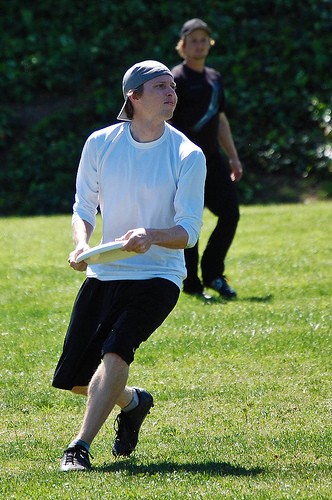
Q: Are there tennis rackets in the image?
A: No, there are no tennis rackets.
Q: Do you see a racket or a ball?
A: No, there are no rackets or balls.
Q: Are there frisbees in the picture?
A: Yes, there is a frisbee.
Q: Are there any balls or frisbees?
A: Yes, there is a frisbee.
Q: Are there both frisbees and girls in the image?
A: No, there is a frisbee but no girls.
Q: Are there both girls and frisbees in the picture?
A: No, there is a frisbee but no girls.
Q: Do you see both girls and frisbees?
A: No, there is a frisbee but no girls.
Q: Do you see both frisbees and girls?
A: No, there is a frisbee but no girls.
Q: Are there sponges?
A: No, there are no sponges.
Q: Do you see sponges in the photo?
A: No, there are no sponges.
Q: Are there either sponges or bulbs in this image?
A: No, there are no sponges or bulbs.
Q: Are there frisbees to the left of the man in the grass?
A: Yes, there is a frisbee to the left of the man.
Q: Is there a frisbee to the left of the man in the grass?
A: Yes, there is a frisbee to the left of the man.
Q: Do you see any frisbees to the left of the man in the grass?
A: Yes, there is a frisbee to the left of the man.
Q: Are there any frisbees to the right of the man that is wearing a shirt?
A: No, the frisbee is to the left of the man.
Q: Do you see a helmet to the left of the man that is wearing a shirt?
A: No, there is a frisbee to the left of the man.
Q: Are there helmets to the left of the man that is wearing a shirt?
A: No, there is a frisbee to the left of the man.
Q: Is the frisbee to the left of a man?
A: Yes, the frisbee is to the left of a man.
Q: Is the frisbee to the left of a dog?
A: No, the frisbee is to the left of a man.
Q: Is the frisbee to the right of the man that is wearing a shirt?
A: No, the frisbee is to the left of the man.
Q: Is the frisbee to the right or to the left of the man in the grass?
A: The frisbee is to the left of the man.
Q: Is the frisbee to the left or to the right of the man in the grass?
A: The frisbee is to the left of the man.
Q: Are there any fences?
A: No, there are no fences.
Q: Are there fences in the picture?
A: No, there are no fences.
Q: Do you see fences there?
A: No, there are no fences.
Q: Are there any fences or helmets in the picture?
A: No, there are no fences or helmets.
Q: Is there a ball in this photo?
A: No, there are no balls.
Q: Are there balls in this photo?
A: No, there are no balls.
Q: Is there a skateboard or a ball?
A: No, there are no balls or skateboards.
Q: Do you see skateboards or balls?
A: No, there are no balls or skateboards.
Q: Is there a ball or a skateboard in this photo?
A: No, there are no balls or skateboards.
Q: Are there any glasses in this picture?
A: No, there are no glasses.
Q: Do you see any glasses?
A: No, there are no glasses.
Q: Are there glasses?
A: No, there are no glasses.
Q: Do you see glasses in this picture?
A: No, there are no glasses.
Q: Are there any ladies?
A: No, there are no ladies.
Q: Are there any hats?
A: Yes, there is a hat.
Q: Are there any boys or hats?
A: Yes, there is a hat.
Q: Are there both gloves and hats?
A: No, there is a hat but no gloves.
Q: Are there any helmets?
A: No, there are no helmets.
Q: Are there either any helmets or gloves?
A: No, there are no helmets or gloves.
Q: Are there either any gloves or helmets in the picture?
A: No, there are no helmets or gloves.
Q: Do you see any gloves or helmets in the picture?
A: No, there are no helmets or gloves.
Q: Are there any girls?
A: No, there are no girls.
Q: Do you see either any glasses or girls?
A: No, there are no girls or glasses.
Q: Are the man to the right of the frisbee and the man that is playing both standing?
A: Yes, both the man and the man are standing.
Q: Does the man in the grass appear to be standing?
A: Yes, the man is standing.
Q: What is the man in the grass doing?
A: The man is standing.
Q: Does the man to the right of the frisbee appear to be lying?
A: No, the man is standing.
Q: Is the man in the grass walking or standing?
A: The man is standing.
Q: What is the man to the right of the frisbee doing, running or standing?
A: The man is standing.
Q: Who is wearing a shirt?
A: The man is wearing a shirt.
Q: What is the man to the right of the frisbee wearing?
A: The man is wearing a shirt.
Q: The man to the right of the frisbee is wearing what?
A: The man is wearing a shirt.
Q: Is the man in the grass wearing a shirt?
A: Yes, the man is wearing a shirt.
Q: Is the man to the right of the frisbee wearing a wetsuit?
A: No, the man is wearing a shirt.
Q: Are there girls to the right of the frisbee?
A: No, there is a man to the right of the frisbee.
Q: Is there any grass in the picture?
A: Yes, there is grass.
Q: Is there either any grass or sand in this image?
A: Yes, there is grass.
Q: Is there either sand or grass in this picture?
A: Yes, there is grass.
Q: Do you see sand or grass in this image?
A: Yes, there is grass.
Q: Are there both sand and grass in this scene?
A: No, there is grass but no sand.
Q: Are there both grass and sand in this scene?
A: No, there is grass but no sand.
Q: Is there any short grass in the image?
A: Yes, there is short grass.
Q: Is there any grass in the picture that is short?
A: Yes, there is grass that is short.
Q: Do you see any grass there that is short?
A: Yes, there is grass that is short.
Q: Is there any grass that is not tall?
A: Yes, there is short grass.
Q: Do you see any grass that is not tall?
A: Yes, there is short grass.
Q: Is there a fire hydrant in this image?
A: No, there are no fire hydrants.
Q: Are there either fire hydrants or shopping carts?
A: No, there are no fire hydrants or shopping carts.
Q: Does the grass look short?
A: Yes, the grass is short.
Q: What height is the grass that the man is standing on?
A: The grass is short.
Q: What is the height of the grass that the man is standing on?
A: The grass is short.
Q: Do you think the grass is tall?
A: No, the grass is short.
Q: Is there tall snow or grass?
A: No, there is grass but it is short.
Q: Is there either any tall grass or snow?
A: No, there is grass but it is short.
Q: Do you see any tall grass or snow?
A: No, there is grass but it is short.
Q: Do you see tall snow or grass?
A: No, there is grass but it is short.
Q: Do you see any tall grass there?
A: No, there is grass but it is short.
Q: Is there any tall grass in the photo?
A: No, there is grass but it is short.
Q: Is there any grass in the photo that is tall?
A: No, there is grass but it is short.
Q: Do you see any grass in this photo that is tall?
A: No, there is grass but it is short.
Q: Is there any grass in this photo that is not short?
A: No, there is grass but it is short.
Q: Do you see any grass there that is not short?
A: No, there is grass but it is short.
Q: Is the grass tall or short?
A: The grass is short.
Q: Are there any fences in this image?
A: No, there are no fences.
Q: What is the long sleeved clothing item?
A: The clothing item is a shirt.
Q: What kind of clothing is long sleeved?
A: The clothing is a shirt.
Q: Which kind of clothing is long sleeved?
A: The clothing is a shirt.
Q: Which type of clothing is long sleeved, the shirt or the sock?
A: The shirt is long sleeved.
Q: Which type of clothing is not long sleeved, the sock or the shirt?
A: The sock is not long sleeved.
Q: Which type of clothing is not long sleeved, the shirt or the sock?
A: The sock is not long sleeved.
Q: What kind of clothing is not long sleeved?
A: The clothing is a sock.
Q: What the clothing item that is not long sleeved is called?
A: The clothing item is a sock.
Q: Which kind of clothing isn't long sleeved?
A: The clothing is a sock.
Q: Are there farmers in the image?
A: No, there are no farmers.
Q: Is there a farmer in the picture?
A: No, there are no farmers.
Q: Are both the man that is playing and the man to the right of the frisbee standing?
A: Yes, both the man and the man are standing.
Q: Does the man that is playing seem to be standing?
A: Yes, the man is standing.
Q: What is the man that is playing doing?
A: The man is standing.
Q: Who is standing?
A: The man is standing.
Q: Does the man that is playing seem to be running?
A: No, the man is standing.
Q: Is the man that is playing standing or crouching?
A: The man is standing.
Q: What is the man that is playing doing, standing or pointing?
A: The man is standing.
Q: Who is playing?
A: The man is playing.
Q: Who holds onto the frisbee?
A: The man holds onto the frisbee.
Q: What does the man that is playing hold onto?
A: The man holds onto the frisbee.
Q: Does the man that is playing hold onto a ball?
A: No, the man holds onto the frisbee.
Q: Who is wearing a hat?
A: The man is wearing a hat.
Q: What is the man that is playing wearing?
A: The man is wearing a hat.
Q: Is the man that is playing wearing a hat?
A: Yes, the man is wearing a hat.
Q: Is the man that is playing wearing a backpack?
A: No, the man is wearing a hat.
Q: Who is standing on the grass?
A: The man is standing on the grass.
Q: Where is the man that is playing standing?
A: The man is standing on the grass.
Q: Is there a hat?
A: Yes, there is a hat.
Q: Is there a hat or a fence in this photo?
A: Yes, there is a hat.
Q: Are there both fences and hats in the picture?
A: No, there is a hat but no fences.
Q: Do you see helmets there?
A: No, there are no helmets.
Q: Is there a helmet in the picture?
A: No, there are no helmets.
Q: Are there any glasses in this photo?
A: No, there are no glasses.